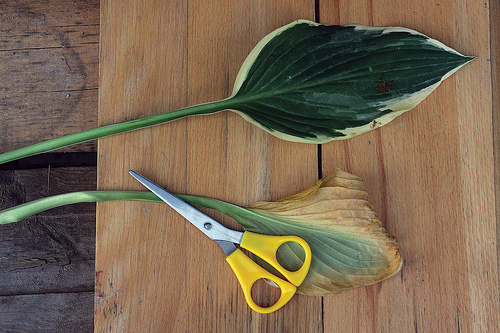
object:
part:
[243, 264, 254, 273]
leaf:
[0, 17, 481, 164]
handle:
[223, 230, 312, 315]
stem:
[0, 189, 240, 225]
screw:
[399, 267, 404, 285]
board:
[95, 0, 500, 333]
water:
[305, 89, 374, 121]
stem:
[0, 97, 230, 163]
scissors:
[126, 168, 315, 316]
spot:
[0, 2, 90, 154]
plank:
[0, 0, 98, 153]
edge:
[126, 169, 241, 243]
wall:
[0, 164, 101, 333]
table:
[96, 2, 498, 331]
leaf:
[1, 165, 412, 298]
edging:
[233, 60, 476, 145]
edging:
[226, 18, 487, 100]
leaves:
[229, 20, 481, 147]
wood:
[94, 1, 499, 331]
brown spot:
[293, 199, 346, 223]